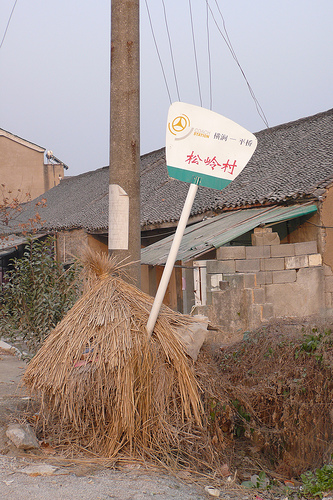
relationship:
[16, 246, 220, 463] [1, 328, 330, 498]
straw stacked on ground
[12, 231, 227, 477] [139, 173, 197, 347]
straw at bottom of post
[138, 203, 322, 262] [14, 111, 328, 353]
awning on house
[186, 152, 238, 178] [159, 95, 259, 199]
characters on sign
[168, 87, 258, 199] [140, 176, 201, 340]
sign on pole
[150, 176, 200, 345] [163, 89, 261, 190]
pole holding sign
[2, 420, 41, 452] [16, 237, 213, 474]
rock piled next to straw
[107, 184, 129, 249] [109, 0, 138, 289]
paper on a pole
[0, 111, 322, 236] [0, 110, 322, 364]
roof on a house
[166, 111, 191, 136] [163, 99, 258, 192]
symbol on a sign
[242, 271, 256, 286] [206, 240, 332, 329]
brick on wall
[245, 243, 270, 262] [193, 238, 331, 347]
brick on wall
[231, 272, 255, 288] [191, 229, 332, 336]
brick on wall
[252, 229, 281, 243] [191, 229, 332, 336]
brick on wall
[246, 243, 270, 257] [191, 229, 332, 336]
brick on wall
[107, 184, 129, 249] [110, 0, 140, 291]
paper on pole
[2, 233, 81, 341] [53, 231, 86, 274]
bush by wall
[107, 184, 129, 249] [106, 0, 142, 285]
paper on pole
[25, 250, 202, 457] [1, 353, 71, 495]
haystack beside road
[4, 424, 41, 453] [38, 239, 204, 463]
rock beside haystack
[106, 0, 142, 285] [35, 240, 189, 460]
pole by haystack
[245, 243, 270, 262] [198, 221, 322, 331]
brick on wall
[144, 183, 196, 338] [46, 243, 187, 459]
pole in haystack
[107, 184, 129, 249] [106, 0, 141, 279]
paper on post